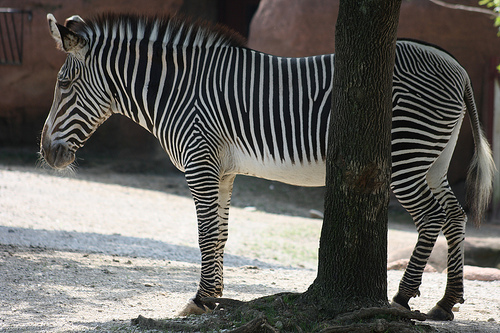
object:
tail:
[458, 76, 499, 226]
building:
[2, 0, 500, 108]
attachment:
[0, 4, 34, 66]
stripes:
[195, 206, 220, 246]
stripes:
[146, 44, 222, 116]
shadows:
[0, 226, 309, 315]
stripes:
[307, 53, 333, 162]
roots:
[130, 290, 443, 332]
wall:
[8, 6, 495, 204]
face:
[37, 58, 118, 171]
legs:
[176, 153, 237, 307]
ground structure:
[0, 156, 499, 331]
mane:
[80, 12, 238, 49]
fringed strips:
[73, 16, 229, 36]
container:
[0, 8, 31, 64]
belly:
[231, 148, 334, 187]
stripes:
[89, 39, 127, 77]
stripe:
[133, 39, 149, 119]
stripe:
[109, 34, 120, 116]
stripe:
[182, 129, 205, 149]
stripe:
[390, 102, 452, 123]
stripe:
[389, 178, 431, 205]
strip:
[183, 155, 215, 175]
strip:
[300, 56, 311, 162]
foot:
[424, 297, 468, 320]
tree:
[127, 2, 431, 333]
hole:
[446, 234, 464, 269]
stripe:
[260, 52, 274, 156]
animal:
[36, 13, 499, 322]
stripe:
[249, 48, 261, 156]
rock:
[101, 269, 113, 275]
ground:
[0, 160, 500, 332]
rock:
[112, 259, 132, 264]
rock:
[65, 265, 71, 268]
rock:
[269, 268, 276, 272]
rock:
[270, 282, 276, 286]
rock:
[144, 283, 153, 288]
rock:
[485, 316, 498, 323]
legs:
[388, 161, 470, 312]